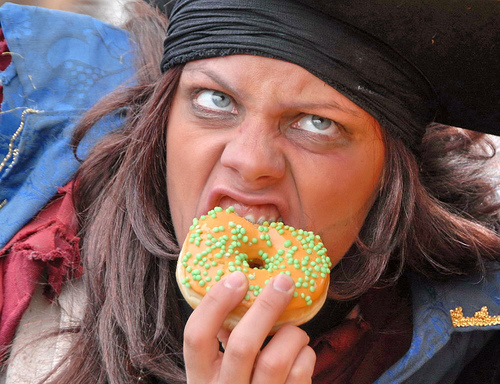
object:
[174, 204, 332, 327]
donut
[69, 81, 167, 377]
hair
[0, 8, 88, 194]
cloth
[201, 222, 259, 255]
sprinkles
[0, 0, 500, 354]
woman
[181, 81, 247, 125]
eyes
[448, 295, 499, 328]
design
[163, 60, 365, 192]
skin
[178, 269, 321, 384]
hand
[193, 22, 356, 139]
up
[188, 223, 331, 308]
icing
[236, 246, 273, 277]
hole